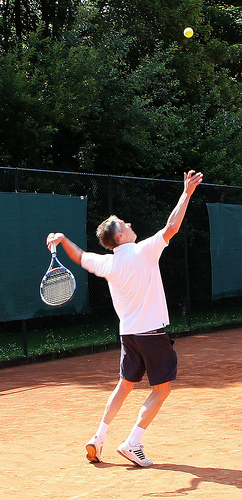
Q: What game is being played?
A: Tennis.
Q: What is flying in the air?
A: Ball.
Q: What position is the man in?
A: Standing.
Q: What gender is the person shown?
A: Male.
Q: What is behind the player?
A: Fence.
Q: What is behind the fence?
A: Trees.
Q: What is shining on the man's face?
A: Sun.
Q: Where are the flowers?
A: Beside the fence.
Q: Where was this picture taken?
A: On a tennis court.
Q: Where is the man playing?
A: On an outdoor court.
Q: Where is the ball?
A: It has been tossed in the air.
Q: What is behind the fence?
A: Trees.